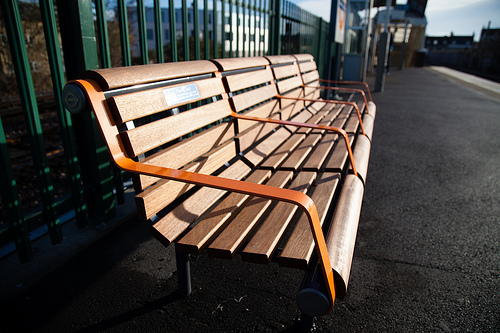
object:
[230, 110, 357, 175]
arm rest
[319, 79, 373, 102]
arm rest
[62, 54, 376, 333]
bench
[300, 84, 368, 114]
arm rest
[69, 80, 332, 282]
arm rest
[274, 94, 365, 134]
arm rest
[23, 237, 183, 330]
shadow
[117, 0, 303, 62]
building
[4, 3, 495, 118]
background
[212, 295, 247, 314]
cigarette butts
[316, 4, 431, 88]
train station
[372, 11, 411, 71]
opening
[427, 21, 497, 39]
tops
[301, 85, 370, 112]
chair arms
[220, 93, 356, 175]
arms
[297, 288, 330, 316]
end cap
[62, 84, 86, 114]
end cap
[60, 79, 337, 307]
arm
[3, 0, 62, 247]
fencing slats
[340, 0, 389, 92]
phone booth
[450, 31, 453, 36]
chimneys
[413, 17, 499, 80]
buildings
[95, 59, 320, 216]
back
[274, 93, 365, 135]
arms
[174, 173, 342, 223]
shadows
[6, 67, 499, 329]
pavement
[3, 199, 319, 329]
under bench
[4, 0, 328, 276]
fence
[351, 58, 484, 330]
sidewalk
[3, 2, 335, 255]
gate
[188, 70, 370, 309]
row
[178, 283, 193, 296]
feet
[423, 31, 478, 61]
house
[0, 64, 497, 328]
walk area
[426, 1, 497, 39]
sky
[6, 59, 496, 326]
street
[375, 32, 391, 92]
pole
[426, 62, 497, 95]
curb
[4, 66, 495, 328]
road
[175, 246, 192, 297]
pole